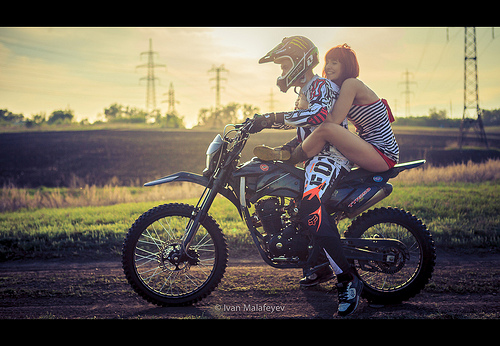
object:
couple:
[253, 36, 407, 274]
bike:
[121, 119, 435, 308]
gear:
[263, 238, 291, 253]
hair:
[327, 47, 361, 77]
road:
[3, 256, 495, 317]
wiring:
[409, 30, 461, 79]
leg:
[291, 123, 382, 174]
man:
[264, 38, 368, 313]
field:
[2, 121, 494, 178]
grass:
[4, 176, 154, 208]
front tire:
[120, 203, 229, 304]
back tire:
[346, 205, 436, 303]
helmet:
[258, 35, 321, 89]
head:
[280, 56, 311, 85]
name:
[220, 303, 286, 315]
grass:
[4, 204, 125, 253]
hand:
[247, 115, 274, 132]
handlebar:
[261, 118, 270, 126]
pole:
[454, 28, 492, 147]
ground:
[448, 142, 494, 160]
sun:
[216, 28, 272, 61]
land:
[3, 184, 249, 239]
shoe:
[338, 272, 363, 315]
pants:
[299, 159, 350, 279]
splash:
[303, 183, 326, 201]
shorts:
[371, 145, 398, 169]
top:
[347, 102, 401, 157]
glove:
[247, 113, 276, 133]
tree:
[50, 107, 72, 126]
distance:
[1, 82, 150, 131]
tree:
[104, 103, 115, 122]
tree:
[428, 106, 447, 121]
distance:
[390, 68, 493, 120]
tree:
[198, 107, 226, 123]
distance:
[100, 79, 287, 121]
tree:
[33, 111, 46, 124]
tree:
[2, 110, 22, 126]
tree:
[484, 108, 500, 124]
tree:
[243, 103, 259, 119]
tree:
[152, 106, 171, 126]